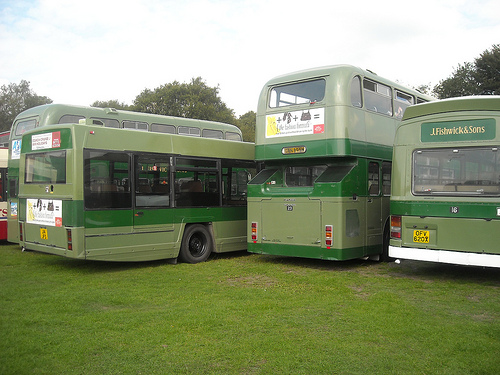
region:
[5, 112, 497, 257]
a row of green busses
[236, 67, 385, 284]
this bus is a double decker bus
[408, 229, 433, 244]
yellow license plate on the back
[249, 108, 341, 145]
a sign on the double decker bus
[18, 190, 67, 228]
an advertisement on the bus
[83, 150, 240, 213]
the bus has many windows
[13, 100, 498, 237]
these busses have two different colors of green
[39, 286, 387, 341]
the grass is green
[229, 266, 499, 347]
gravel showing through the grass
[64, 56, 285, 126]
trees in the background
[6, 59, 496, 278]
four green buses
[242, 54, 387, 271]
back of green double decker bus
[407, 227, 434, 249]
yellow license plate on the back of green bus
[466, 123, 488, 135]
yellow lettered Sons sign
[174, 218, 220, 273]
round black bus tire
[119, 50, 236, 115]
dark green tree leaves with white clouds behind them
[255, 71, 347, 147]
white advertisement on the back of a double decker bus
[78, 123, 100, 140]
orange light on top of the right side of a bus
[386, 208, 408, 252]
rectangular bus taillights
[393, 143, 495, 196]
rectangular back bus window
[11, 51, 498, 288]
the buses are green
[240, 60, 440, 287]
the bus has two levels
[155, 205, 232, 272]
the bus has a black tire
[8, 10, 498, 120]
the sky is cloudy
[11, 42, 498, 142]
the trees are green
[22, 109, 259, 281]
the bus has big windows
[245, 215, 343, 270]
the bus has red tail lights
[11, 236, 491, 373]
the grass is green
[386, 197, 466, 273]
the license plate is yellow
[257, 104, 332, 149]
the back of the bus has an advertisement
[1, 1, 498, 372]
a bus storage yard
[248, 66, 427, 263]
a double decker bus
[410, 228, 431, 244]
the vehicles license plate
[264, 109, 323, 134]
advertising banner on the bus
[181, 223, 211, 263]
the rear wheel of the bus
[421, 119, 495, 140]
the company's name and logo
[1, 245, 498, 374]
the green grass of the storage yard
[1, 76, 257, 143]
trees in the distance above the buses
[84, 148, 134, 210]
large passenger viewing windows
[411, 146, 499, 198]
the rear window of the bus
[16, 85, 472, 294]
four green buses parked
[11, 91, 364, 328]
three green buses with advertisements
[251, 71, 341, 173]
white sign on green bus with yellow and red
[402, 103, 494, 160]
green sign with yellow lettering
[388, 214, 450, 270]
yellow license plate on green bus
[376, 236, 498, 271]
white bumper on green bus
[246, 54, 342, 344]
bus has two stories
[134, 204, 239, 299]
one black tire visible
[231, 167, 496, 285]
buses olive green with dark green trim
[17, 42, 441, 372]
buses parked on grass